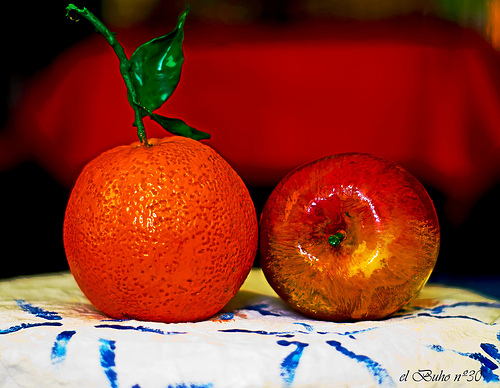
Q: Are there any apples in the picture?
A: Yes, there is an apple.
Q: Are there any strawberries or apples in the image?
A: Yes, there is an apple.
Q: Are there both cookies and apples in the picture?
A: No, there is an apple but no cookies.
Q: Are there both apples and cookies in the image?
A: No, there is an apple but no cookies.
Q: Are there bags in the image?
A: No, there are no bags.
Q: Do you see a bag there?
A: No, there are no bags.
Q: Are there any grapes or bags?
A: No, there are no bags or grapes.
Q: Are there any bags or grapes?
A: No, there are no bags or grapes.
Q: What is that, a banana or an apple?
A: That is an apple.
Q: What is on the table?
A: The apple is on the table.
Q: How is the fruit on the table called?
A: The fruit is an apple.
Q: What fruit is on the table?
A: The fruit is an apple.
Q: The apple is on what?
A: The apple is on the table.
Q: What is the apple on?
A: The apple is on the table.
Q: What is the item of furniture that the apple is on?
A: The piece of furniture is a table.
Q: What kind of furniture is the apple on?
A: The apple is on the table.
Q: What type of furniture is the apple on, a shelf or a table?
A: The apple is on a table.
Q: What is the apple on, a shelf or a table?
A: The apple is on a table.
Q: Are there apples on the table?
A: Yes, there is an apple on the table.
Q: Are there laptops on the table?
A: No, there is an apple on the table.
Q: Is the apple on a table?
A: Yes, the apple is on a table.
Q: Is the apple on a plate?
A: No, the apple is on a table.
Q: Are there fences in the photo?
A: No, there are no fences.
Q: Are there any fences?
A: No, there are no fences.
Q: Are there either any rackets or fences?
A: No, there are no fences or rackets.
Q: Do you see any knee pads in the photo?
A: No, there are no knee pads.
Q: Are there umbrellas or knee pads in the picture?
A: No, there are no knee pads or umbrellas.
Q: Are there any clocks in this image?
A: No, there are no clocks.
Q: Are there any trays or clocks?
A: No, there are no clocks or trays.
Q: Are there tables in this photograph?
A: Yes, there is a table.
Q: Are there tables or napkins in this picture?
A: Yes, there is a table.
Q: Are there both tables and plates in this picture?
A: No, there is a table but no plates.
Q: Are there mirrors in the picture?
A: No, there are no mirrors.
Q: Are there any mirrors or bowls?
A: No, there are no mirrors or bowls.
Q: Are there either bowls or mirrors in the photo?
A: No, there are no mirrors or bowls.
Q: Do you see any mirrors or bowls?
A: No, there are no mirrors or bowls.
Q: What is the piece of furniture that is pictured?
A: The piece of furniture is a table.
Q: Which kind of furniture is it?
A: The piece of furniture is a table.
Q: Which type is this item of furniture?
A: This is a table.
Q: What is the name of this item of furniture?
A: This is a table.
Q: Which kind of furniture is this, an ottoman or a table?
A: This is a table.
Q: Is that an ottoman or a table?
A: That is a table.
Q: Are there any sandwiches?
A: No, there are no sandwiches.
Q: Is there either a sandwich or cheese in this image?
A: No, there are no sandwiches or cheese.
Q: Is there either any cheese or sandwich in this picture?
A: No, there are no sandwiches or cheese.